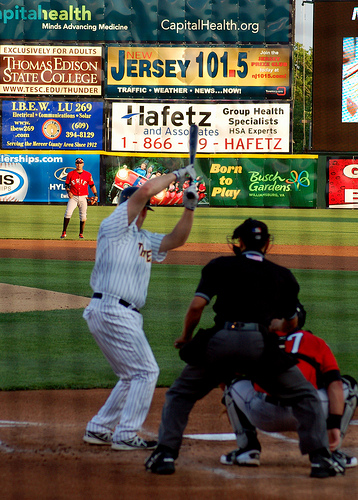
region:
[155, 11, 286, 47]
CapitalHealth.org on banner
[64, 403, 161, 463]
player is wearing shoes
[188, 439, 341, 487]
umpires wearing special shoes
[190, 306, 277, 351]
umpire with reflective belt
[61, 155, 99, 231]
player wearing red uniform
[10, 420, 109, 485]
ground is a clean brown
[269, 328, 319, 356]
red shirt with 7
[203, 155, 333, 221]
born to play busch gardens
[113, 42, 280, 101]
new jersey 101.5 banner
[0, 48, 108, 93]
thomas edison state college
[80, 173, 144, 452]
man wearing stripe shirt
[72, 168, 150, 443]
man wearing stripe pants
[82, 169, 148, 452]
man wearing a helmet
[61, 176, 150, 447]
man wearing white gloves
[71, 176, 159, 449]
man wearing black shoes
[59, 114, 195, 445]
man holding a bat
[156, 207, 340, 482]
man wearing black shirt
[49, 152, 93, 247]
man wearing a cap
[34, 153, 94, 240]
man wearing red shirt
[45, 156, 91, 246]
man wearing white pants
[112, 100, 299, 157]
ad on the back wall of the baseball diamond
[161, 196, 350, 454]
umpire behind the plate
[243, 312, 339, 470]
catcher down and ready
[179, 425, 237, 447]
home plate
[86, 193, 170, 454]
batter ready for the pitch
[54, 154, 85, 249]
infielder back on the grass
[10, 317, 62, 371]
green grass on the infield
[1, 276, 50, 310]
pitcher's mound in the infield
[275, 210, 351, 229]
shadow on the grass in the outfield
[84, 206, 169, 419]
player wearing a striped uniform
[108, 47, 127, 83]
letter on a sign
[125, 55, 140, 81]
letter on a sign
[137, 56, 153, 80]
letter on a sign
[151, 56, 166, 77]
letter on a sign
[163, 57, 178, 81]
letter on a sign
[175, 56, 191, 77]
letter on a sign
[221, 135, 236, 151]
letter on a sign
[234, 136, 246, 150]
letter on a sign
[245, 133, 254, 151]
letter on a sign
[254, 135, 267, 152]
letter on a sign